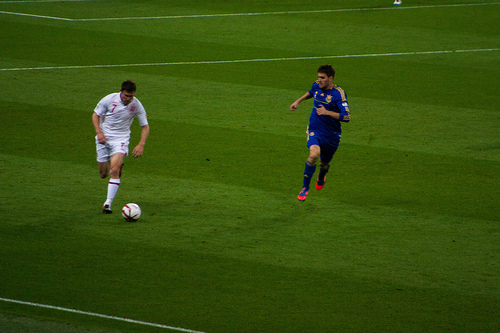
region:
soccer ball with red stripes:
[121, 204, 142, 220]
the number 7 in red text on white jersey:
[110, 101, 117, 113]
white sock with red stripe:
[100, 178, 121, 212]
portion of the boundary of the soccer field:
[0, 293, 205, 331]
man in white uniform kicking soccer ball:
[89, 79, 154, 225]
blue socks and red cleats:
[294, 159, 315, 201]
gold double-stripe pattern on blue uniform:
[333, 86, 345, 102]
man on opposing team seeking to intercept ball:
[287, 65, 352, 200]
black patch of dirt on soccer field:
[204, 156, 210, 161]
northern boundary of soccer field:
[1, 44, 499, 73]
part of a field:
[306, 235, 317, 247]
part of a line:
[33, 292, 70, 321]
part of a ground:
[205, 273, 248, 318]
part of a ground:
[175, 225, 215, 267]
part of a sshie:
[289, 183, 312, 210]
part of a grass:
[220, 200, 273, 243]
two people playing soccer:
[27, 9, 460, 304]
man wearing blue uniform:
[282, 82, 354, 164]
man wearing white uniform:
[75, 82, 155, 162]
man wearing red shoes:
[282, 178, 334, 206]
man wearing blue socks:
[297, 154, 330, 191]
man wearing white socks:
[92, 168, 124, 210]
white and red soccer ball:
[96, 185, 152, 238]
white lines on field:
[5, 5, 475, 83]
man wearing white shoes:
[94, 184, 116, 216]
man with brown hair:
[115, 78, 146, 109]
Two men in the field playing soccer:
[73, 49, 375, 287]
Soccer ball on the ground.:
[114, 190, 192, 226]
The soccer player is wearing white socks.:
[103, 176, 139, 201]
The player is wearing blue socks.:
[296, 148, 343, 180]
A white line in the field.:
[16, 284, 135, 331]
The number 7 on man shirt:
[93, 90, 125, 117]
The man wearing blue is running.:
[314, 51, 349, 230]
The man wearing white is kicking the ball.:
[72, 55, 156, 232]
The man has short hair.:
[316, 60, 347, 76]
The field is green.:
[208, 173, 480, 303]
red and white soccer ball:
[121, 201, 142, 222]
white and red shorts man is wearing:
[93, 130, 128, 161]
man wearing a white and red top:
[92, 91, 147, 136]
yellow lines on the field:
[0, 1, 499, 331]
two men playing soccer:
[90, 65, 352, 215]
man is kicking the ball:
[91, 79, 153, 215]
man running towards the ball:
[288, 64, 351, 201]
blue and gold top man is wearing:
[306, 83, 352, 135]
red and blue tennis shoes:
[296, 176, 326, 202]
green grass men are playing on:
[0, 1, 499, 331]